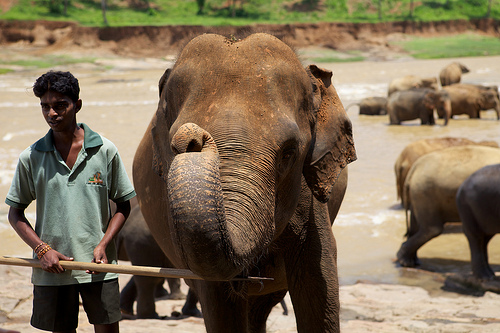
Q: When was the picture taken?
A: Daytime.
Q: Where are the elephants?
A: In the water.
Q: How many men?
A: One.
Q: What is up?
A: The trunk.